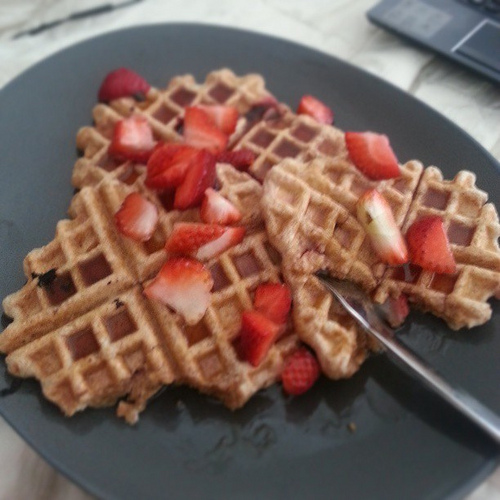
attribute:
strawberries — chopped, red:
[112, 105, 249, 302]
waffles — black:
[13, 66, 474, 452]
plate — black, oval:
[0, 25, 472, 498]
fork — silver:
[320, 273, 497, 463]